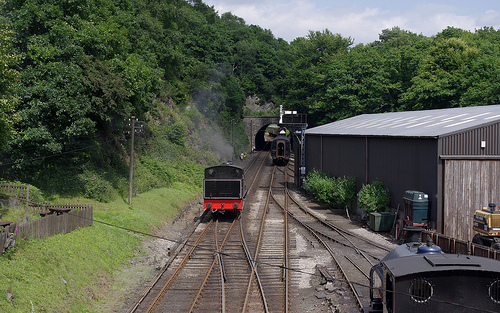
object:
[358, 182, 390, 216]
bush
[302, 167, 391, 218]
bush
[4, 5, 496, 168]
trees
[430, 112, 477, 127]
stripes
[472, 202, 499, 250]
tractor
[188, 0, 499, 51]
sky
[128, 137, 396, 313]
tracks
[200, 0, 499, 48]
clouds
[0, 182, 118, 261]
fence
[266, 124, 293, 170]
train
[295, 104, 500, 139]
roof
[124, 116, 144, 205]
pole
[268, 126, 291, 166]
train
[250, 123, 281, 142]
tunnel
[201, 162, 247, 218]
car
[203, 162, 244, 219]
train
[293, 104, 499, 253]
building